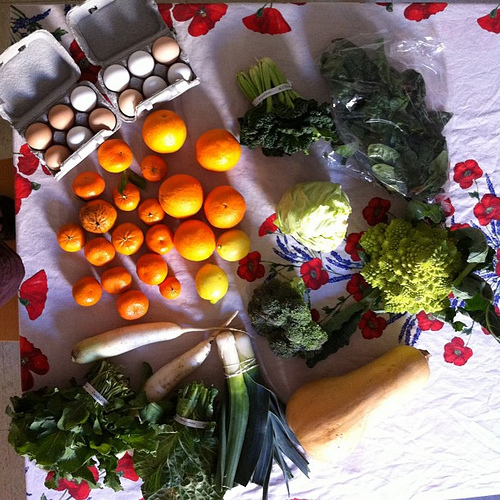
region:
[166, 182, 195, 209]
this is an orange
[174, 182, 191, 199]
the orange yellow in color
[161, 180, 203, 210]
the orange is round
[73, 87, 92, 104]
this is a egg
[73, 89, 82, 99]
the egg is white in color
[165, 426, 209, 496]
this is a vegetable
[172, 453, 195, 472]
the vegetable is green in color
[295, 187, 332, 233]
this is a cabbage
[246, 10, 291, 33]
this is a flower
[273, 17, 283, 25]
the flower is red in color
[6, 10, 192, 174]
brown and white eggs in paper cartons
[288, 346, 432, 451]
orange butternut squash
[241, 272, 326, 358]
crunchy green broccoli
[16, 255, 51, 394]
red poppy pattern on a white tablecloth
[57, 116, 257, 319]
many round oranges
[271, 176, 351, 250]
light green head of lettuce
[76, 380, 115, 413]
paper band holding bouquet of green leafy vegetables together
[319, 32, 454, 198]
clear plastic bag filled with green leafy vegetables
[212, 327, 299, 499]
green and white leeks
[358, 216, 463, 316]
spiny, neon green romanesco cabbage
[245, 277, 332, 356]
the broccoli is green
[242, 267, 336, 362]
broccoli is on the table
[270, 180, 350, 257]
the lettuce is green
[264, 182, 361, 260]
lettuce is on the table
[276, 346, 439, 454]
the squash is orange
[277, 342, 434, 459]
the squash is on the table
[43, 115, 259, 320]
there are many oranges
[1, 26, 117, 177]
half a dozen eggs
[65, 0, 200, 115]
half a dozen eggs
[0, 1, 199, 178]
the eggs are on the table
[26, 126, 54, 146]
brown egg in egg carton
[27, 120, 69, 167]
brown egg next to brown egg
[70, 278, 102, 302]
small round orange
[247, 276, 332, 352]
head of green brocolli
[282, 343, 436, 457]
large tan squash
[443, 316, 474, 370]
red flower decoration with leaf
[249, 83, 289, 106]
white tag with lettering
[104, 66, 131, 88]
white smooth egg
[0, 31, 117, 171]
grey paper egg carton open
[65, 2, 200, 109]
grey paper egg carton open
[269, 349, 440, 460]
Nice size squash on table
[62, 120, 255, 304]
Various size oranges laid out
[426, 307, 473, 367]
Red flowers on tablecloth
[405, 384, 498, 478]
Background of tablecloth is white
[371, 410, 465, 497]
Several wrinkles in tablecloth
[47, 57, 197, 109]
Eggs in brown carton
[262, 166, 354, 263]
Small head of lettuce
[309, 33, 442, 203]
Green leaves in plastic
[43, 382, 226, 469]
Herbs in white twist ties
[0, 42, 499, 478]
Healthy foods laid out